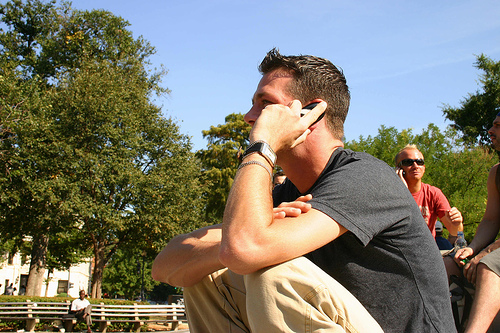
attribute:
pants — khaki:
[183, 255, 384, 332]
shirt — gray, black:
[274, 148, 456, 332]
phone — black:
[301, 100, 325, 128]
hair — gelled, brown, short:
[257, 45, 350, 139]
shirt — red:
[410, 180, 451, 238]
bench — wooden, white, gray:
[1, 300, 189, 332]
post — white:
[172, 302, 178, 321]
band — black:
[241, 141, 263, 158]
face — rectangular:
[261, 142, 278, 167]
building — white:
[0, 221, 94, 298]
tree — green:
[1, 2, 184, 299]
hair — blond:
[395, 142, 418, 166]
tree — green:
[84, 113, 202, 298]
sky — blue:
[1, 1, 500, 217]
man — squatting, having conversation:
[180, 55, 453, 332]